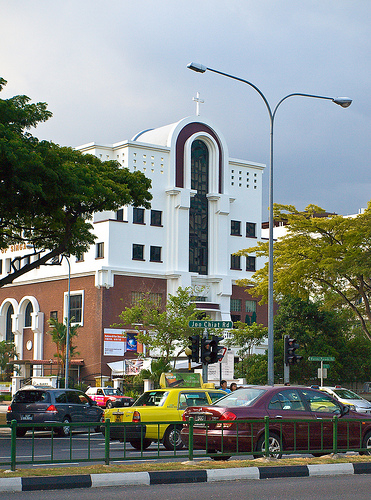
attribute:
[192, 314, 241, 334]
sign — green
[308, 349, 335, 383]
signs — green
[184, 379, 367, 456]
car — red, yellow, taxi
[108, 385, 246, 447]
car — taxi, yellow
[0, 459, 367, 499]
barrier — black, white, striped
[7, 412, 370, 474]
fence — metal, green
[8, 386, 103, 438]
car — blue, mini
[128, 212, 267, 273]
windows — doubled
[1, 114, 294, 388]
building — bricked, white, red, huge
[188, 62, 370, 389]
light — tall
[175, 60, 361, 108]
lamps — silver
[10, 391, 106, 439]
van — gray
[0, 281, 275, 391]
bricks — red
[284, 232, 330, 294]
leaves — green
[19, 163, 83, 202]
leaves — dark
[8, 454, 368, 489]
curb — white, black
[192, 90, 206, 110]
cross — light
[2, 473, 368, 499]
asphalt — gray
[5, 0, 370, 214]
sky — blue, cloudy